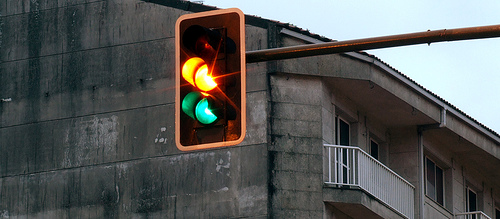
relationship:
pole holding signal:
[235, 24, 499, 63] [171, 3, 254, 151]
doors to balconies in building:
[334, 104, 358, 189] [3, 1, 497, 217]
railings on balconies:
[327, 142, 497, 217] [323, 79, 497, 217]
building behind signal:
[3, 1, 497, 217] [171, 3, 254, 151]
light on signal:
[194, 63, 216, 90] [174, 7, 247, 151]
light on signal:
[195, 100, 216, 123] [174, 7, 247, 151]